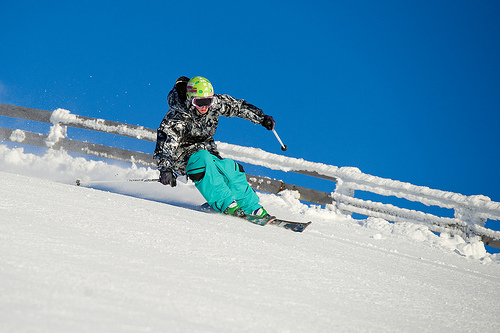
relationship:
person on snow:
[77, 45, 426, 320] [0, 145, 498, 331]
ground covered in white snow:
[0, 168, 498, 329] [0, 171, 498, 331]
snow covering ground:
[1, 172, 498, 330] [6, 148, 498, 329]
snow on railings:
[344, 164, 489, 202] [2, 106, 498, 247]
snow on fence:
[0, 145, 498, 331] [0, 104, 499, 251]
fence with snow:
[286, 130, 498, 280] [355, 166, 480, 206]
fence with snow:
[0, 104, 499, 251] [0, 103, 499, 248]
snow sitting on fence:
[0, 103, 499, 248] [0, 104, 499, 251]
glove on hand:
[248, 108, 277, 130] [258, 108, 277, 130]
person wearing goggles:
[151, 75, 276, 227] [190, 95, 214, 106]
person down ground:
[151, 75, 276, 227] [0, 147, 498, 331]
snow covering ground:
[1, 172, 498, 330] [0, 147, 498, 331]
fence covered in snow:
[0, 104, 499, 251] [213, 138, 497, 248]